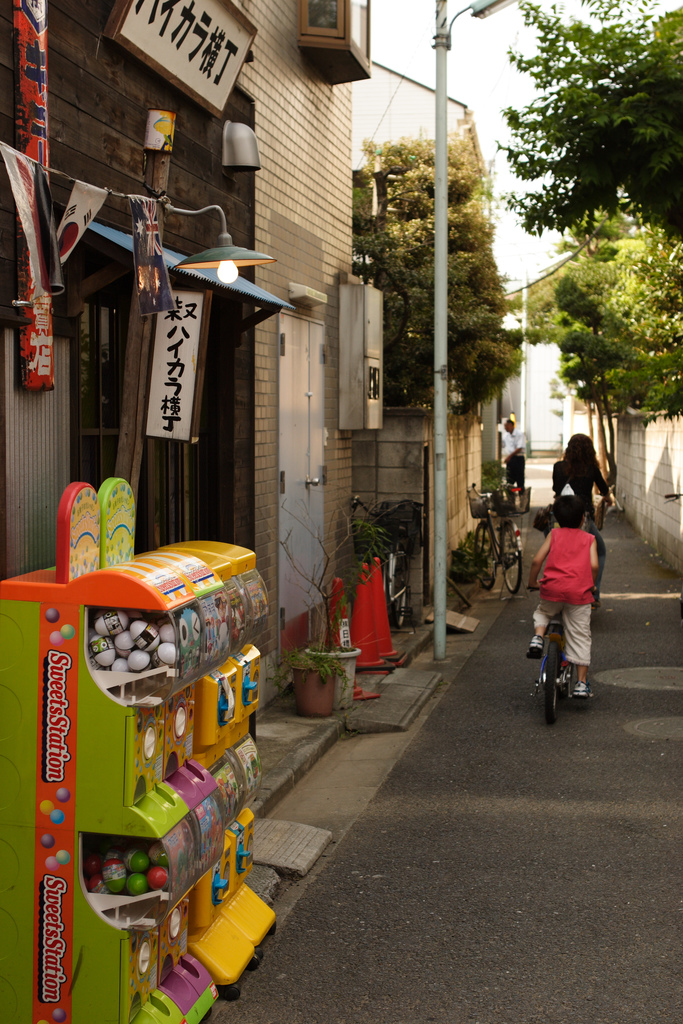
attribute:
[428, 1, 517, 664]
light pole — tall, gray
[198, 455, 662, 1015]
road — long, paved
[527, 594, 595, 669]
shorts — long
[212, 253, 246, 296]
light bulb — lit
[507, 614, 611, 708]
bicycle — parked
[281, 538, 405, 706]
cones — orange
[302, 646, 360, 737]
flower pot — brown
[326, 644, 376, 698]
flower pot — grey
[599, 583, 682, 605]
light — shining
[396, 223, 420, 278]
leaves — green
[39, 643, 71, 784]
writing — red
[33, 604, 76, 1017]
background — orange